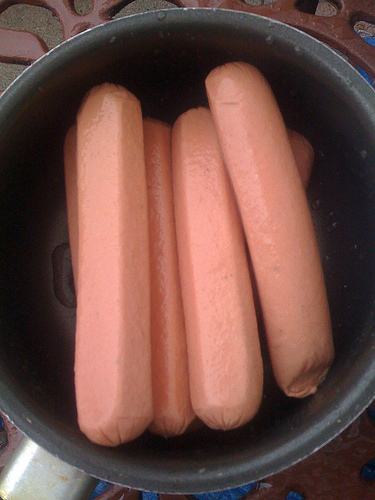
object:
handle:
[0, 439, 92, 500]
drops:
[265, 34, 275, 46]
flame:
[95, 491, 261, 499]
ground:
[270, 124, 295, 158]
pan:
[0, 5, 375, 500]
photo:
[2, 4, 373, 499]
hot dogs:
[246, 129, 314, 319]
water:
[316, 188, 361, 259]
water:
[158, 29, 164, 39]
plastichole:
[354, 20, 375, 47]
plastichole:
[293, 0, 341, 18]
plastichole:
[0, 3, 65, 52]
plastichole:
[110, 1, 181, 23]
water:
[50, 241, 77, 310]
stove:
[0, 0, 375, 500]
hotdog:
[62, 124, 79, 293]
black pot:
[0, 6, 374, 494]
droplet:
[152, 9, 167, 24]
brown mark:
[51, 471, 74, 487]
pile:
[61, 74, 314, 430]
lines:
[197, 403, 251, 430]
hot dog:
[205, 63, 334, 399]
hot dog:
[171, 106, 264, 430]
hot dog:
[141, 116, 202, 438]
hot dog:
[73, 83, 154, 447]